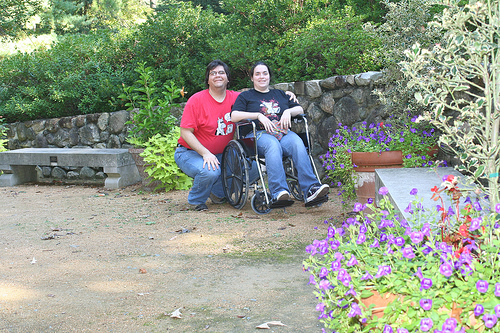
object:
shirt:
[176, 89, 243, 154]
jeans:
[247, 128, 323, 202]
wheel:
[219, 138, 252, 208]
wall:
[4, 101, 188, 180]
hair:
[204, 58, 232, 89]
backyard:
[0, 0, 500, 332]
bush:
[139, 125, 196, 193]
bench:
[0, 146, 144, 191]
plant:
[136, 125, 201, 192]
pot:
[135, 162, 171, 194]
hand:
[257, 112, 282, 135]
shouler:
[268, 87, 289, 97]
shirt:
[231, 87, 304, 137]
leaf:
[257, 322, 274, 330]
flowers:
[418, 297, 435, 313]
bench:
[372, 166, 500, 242]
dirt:
[0, 181, 344, 332]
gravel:
[41, 228, 81, 240]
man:
[174, 58, 263, 211]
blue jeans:
[172, 142, 245, 204]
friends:
[173, 58, 330, 212]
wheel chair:
[217, 101, 333, 216]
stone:
[304, 80, 325, 98]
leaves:
[115, 93, 126, 99]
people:
[231, 60, 333, 204]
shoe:
[303, 183, 331, 206]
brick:
[348, 148, 404, 166]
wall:
[269, 68, 426, 185]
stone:
[107, 110, 129, 137]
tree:
[0, 0, 56, 44]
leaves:
[225, 50, 230, 58]